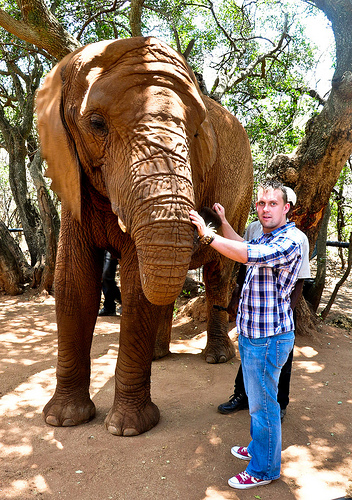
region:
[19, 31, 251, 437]
Brown elephant standing on dirt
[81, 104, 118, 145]
elephant has big dark eye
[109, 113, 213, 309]
very wrinkled elephant trunk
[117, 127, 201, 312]
very big elephant trunk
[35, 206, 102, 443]
elephant has a big leg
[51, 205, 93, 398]
elephant leg has wrinkles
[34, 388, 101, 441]
elephant has big feet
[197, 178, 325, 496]
man wearing a plaid shirt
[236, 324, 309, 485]
man wearing denim pants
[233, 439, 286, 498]
man wearing red athletic shoes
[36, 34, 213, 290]
elephant face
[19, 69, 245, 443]
standing elephant facing camera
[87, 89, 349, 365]
white man standing next to elephant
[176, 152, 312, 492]
white man in blue jeans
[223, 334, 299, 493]
bluejeans and red sneakers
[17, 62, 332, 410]
man touching elephant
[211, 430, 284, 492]
red and white sneakers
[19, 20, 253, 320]
elephant with curled trunk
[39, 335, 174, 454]
thick and wrinkly elephant feet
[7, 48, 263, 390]
elephant at zoo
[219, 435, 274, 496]
Red and white tennis shoes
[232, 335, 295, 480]
Blue jeans on man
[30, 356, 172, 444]
Elephant's two front feet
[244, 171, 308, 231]
Man's face looking at camera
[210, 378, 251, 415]
Black laced shoes of man behind front man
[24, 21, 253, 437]
Elephant standing next to man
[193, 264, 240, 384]
elephant's back left foot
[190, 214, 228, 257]
Bracelet on man's left arm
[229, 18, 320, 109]
Tree branches behind elephant and man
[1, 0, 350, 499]
wooded and shaded zoo enclosure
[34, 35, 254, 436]
brown and wrinkled elephant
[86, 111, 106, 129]
large elephant eye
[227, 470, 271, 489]
maroon and white left shoe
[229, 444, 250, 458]
maroon and white right shoe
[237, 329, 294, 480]
man's faded blue jeans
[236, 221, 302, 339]
short sleeved plaid shirt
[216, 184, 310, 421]
man in black pants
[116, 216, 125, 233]
dirty white elephant tusk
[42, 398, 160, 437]
large front elephant feet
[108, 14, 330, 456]
Picture is taken outside.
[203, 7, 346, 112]
Picture taken during the day time.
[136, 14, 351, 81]
The sun is out.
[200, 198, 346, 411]
A man is touching the elephant's trunk.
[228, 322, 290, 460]
The man is wearing blue jeans.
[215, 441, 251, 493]
The man is wearing red and white shoes.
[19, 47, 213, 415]
The elephant is brown in color.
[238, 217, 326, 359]
The man is wearing a short sleeved shirt.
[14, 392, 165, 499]
The ground is light brown in color.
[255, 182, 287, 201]
The man has short hair.